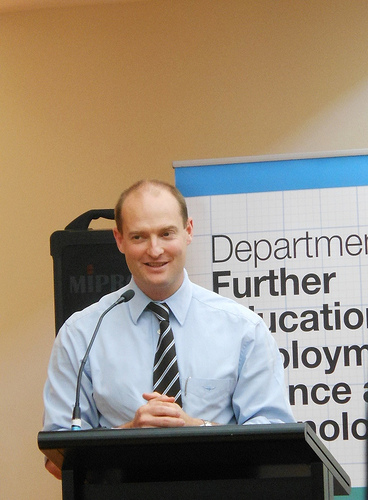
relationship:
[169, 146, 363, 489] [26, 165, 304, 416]
sign behind man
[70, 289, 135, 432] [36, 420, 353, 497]
microphone attached to podium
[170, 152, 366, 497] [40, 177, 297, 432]
screen behind man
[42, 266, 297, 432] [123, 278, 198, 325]
blue shirt has collar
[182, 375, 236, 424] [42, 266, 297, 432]
pocket on front of blue shirt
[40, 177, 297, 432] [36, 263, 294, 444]
man wearing shirt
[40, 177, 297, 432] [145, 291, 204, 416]
man wearing tie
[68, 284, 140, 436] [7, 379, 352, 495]
microphone at podium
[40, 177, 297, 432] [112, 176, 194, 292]
man has head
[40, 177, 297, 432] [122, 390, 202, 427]
man clasping hands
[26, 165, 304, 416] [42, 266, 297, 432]
man wearing blue shirt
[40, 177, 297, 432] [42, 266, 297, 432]
man wearing blue shirt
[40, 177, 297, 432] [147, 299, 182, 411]
man wearing tie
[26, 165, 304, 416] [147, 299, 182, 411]
man wearing tie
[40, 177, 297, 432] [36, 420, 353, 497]
man resting hands on podium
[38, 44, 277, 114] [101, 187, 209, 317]
wall behind man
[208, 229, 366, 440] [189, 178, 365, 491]
writing on sign